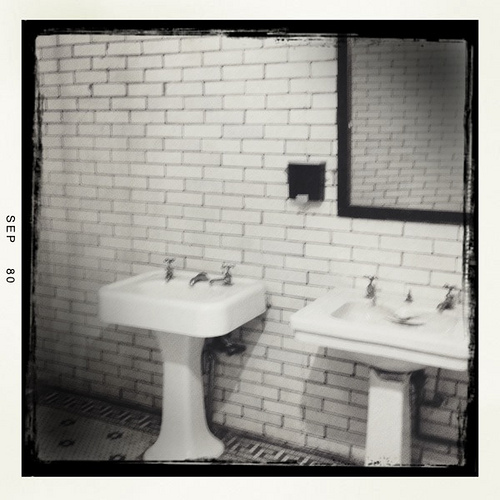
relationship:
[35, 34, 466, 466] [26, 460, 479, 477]
photo with border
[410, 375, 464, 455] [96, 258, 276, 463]
pipes behind sinks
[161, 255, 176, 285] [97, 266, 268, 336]
faucet on sink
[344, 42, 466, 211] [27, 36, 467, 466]
mirror on wall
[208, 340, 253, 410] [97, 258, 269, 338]
pipes connected sink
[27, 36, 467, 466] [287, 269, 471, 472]
wall behind sink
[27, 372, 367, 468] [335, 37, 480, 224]
floor beneath mirror